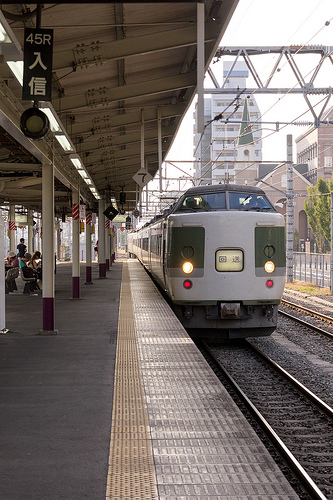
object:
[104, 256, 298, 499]
platform bricks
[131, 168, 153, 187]
sign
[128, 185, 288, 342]
train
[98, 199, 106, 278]
metal post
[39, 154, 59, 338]
metal post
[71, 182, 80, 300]
metal post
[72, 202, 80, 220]
patch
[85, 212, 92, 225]
patch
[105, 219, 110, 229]
patch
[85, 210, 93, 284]
pole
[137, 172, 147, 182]
number 7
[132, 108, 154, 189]
sign post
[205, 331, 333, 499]
road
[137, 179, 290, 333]
boat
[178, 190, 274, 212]
window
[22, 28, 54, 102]
sign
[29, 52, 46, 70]
symbol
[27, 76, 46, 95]
symbol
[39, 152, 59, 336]
column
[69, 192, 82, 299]
column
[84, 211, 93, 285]
column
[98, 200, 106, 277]
column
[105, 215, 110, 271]
column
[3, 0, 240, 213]
awning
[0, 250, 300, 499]
pavement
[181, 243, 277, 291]
light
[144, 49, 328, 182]
wires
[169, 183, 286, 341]
front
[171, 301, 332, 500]
track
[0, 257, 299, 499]
platform